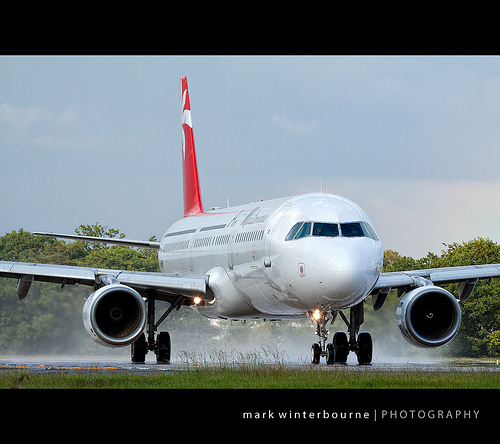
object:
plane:
[0, 77, 498, 366]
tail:
[179, 75, 205, 218]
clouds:
[233, 84, 399, 176]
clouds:
[224, 114, 309, 154]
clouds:
[0, 55, 498, 222]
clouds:
[381, 178, 493, 237]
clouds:
[262, 103, 330, 150]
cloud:
[0, 100, 118, 158]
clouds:
[304, 93, 399, 162]